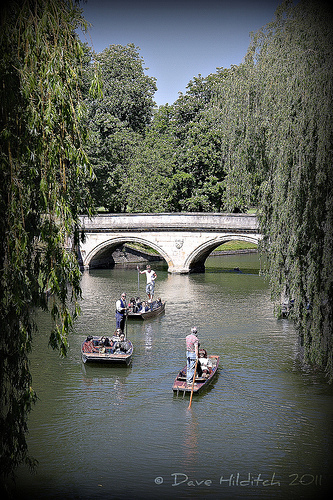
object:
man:
[185, 326, 199, 384]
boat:
[173, 350, 219, 391]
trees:
[0, 1, 105, 465]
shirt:
[185, 334, 199, 354]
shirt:
[115, 299, 125, 326]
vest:
[115, 299, 127, 318]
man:
[138, 265, 155, 300]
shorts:
[145, 282, 156, 294]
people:
[114, 292, 128, 334]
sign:
[153, 472, 322, 490]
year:
[288, 472, 322, 490]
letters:
[171, 470, 189, 487]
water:
[12, 254, 333, 499]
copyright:
[152, 468, 327, 491]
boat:
[122, 294, 163, 318]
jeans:
[185, 352, 198, 387]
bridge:
[60, 210, 266, 272]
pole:
[136, 268, 141, 296]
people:
[82, 335, 98, 357]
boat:
[80, 335, 134, 360]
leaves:
[48, 114, 64, 144]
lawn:
[216, 240, 259, 253]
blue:
[146, 31, 207, 57]